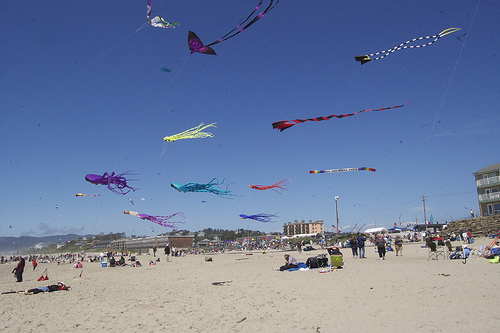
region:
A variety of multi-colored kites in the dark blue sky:
[47, 10, 448, 222]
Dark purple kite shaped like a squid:
[59, 156, 146, 199]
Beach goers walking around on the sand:
[323, 228, 467, 257]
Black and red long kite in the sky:
[260, 98, 412, 138]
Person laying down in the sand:
[28, 270, 82, 315]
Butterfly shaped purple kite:
[175, 28, 230, 64]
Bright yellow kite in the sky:
[152, 103, 229, 152]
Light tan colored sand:
[190, 273, 305, 323]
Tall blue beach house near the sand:
[472, 156, 498, 223]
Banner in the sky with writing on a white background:
[297, 163, 397, 185]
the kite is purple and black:
[181, 25, 223, 67]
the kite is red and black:
[268, 108, 368, 138]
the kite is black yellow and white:
[344, 40, 446, 68]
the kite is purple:
[81, 163, 150, 195]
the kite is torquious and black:
[164, 175, 241, 200]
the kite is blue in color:
[236, 202, 284, 228]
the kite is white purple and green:
[124, 0, 191, 35]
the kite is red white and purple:
[118, 205, 194, 232]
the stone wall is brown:
[438, 210, 494, 237]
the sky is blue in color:
[13, 32, 142, 117]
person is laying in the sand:
[22, 272, 100, 303]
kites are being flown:
[56, 92, 253, 280]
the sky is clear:
[37, 61, 115, 144]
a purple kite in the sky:
[81, 149, 135, 199]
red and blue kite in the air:
[246, 93, 471, 158]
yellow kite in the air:
[156, 105, 232, 152]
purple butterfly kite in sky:
[174, 21, 233, 89]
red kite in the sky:
[244, 172, 289, 211]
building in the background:
[283, 208, 353, 257]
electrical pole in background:
[398, 186, 448, 252]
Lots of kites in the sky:
[67, 8, 407, 217]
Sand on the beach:
[137, 274, 379, 319]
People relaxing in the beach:
[26, 228, 496, 299]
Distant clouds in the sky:
[22, 213, 82, 243]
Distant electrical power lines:
[400, 181, 454, 224]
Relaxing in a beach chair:
[312, 239, 367, 279]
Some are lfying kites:
[345, 222, 407, 257]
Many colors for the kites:
[64, 11, 441, 254]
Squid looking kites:
[82, 143, 294, 213]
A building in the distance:
[107, 230, 202, 263]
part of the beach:
[403, 239, 438, 293]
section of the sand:
[201, 302, 208, 307]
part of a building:
[309, 228, 311, 230]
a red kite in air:
[256, 180, 273, 197]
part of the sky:
[302, 192, 310, 198]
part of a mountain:
[53, 237, 75, 243]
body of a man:
[375, 227, 387, 279]